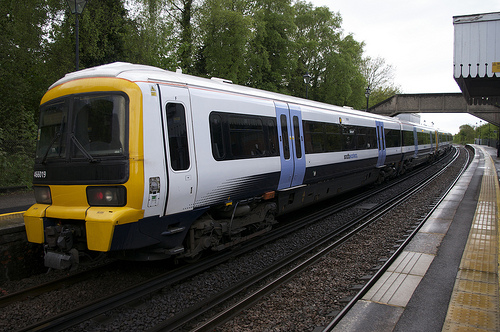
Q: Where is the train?
A: Tracks.